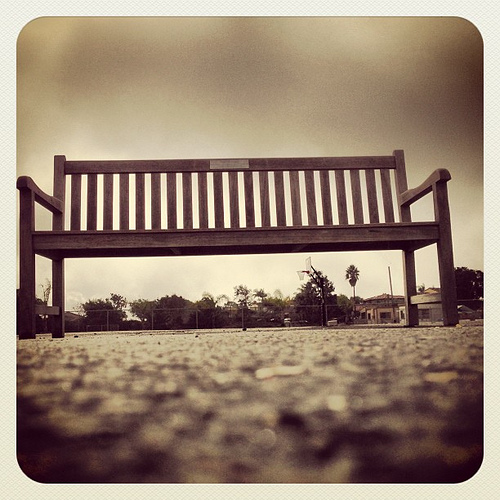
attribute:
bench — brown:
[17, 155, 460, 339]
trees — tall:
[32, 265, 483, 333]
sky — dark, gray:
[17, 17, 483, 320]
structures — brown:
[353, 289, 482, 321]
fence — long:
[68, 302, 366, 327]